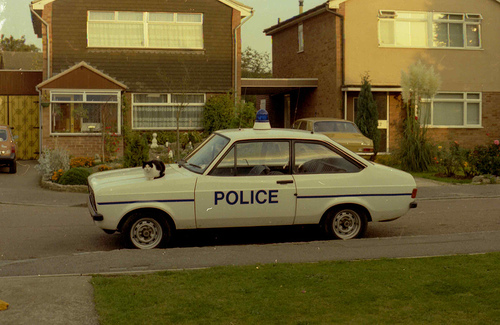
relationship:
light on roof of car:
[249, 109, 272, 129] [90, 127, 430, 256]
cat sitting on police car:
[139, 159, 168, 183] [87, 112, 418, 237]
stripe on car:
[94, 185, 423, 210] [83, 106, 418, 248]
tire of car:
[121, 210, 166, 252] [83, 106, 418, 248]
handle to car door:
[279, 178, 294, 184] [190, 135, 298, 230]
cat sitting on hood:
[138, 155, 169, 185] [82, 157, 194, 192]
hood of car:
[82, 157, 194, 192] [83, 106, 418, 248]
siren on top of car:
[250, 107, 274, 127] [85, 125, 418, 246]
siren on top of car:
[250, 107, 274, 127] [83, 106, 418, 248]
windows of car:
[207, 138, 365, 177] [83, 106, 418, 248]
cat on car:
[139, 159, 163, 179] [85, 125, 418, 246]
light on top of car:
[245, 112, 281, 128] [83, 106, 418, 248]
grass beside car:
[87, 252, 499, 324] [85, 125, 418, 246]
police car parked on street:
[76, 107, 433, 247] [4, 182, 496, 270]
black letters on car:
[210, 187, 285, 211] [83, 106, 418, 248]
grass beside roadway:
[87, 252, 499, 324] [0, 186, 497, 264]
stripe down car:
[99, 188, 416, 205] [83, 106, 418, 248]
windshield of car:
[176, 126, 230, 172] [85, 125, 418, 246]